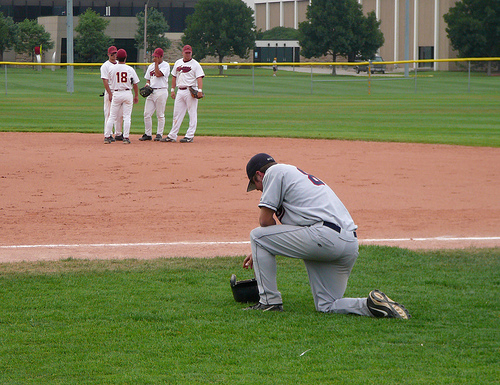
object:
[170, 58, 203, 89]
jersey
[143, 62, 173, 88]
jersey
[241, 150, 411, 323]
baseball player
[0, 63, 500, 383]
ground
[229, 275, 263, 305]
baseball glove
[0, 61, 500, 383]
grass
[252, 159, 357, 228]
uniform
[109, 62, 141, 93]
uniform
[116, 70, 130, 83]
number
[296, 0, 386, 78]
tree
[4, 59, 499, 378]
baseball field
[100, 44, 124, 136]
baseball player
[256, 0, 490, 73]
building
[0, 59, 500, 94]
fence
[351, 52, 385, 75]
van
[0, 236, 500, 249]
line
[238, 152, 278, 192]
hat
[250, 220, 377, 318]
pants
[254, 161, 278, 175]
hair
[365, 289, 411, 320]
shoe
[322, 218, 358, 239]
belt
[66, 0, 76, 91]
pole